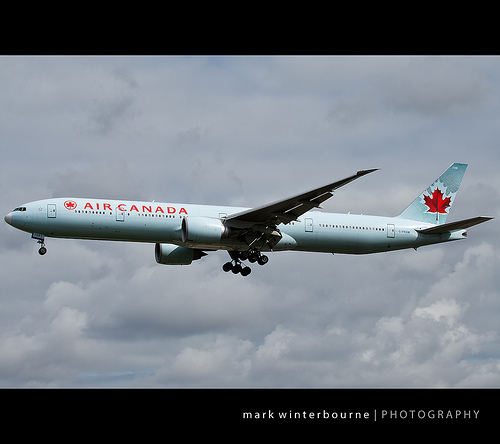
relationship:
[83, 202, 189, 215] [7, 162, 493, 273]
air canada written in plane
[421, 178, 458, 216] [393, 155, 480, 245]
logo on tail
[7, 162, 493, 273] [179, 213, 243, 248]
plane has engine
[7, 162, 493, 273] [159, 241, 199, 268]
plane has engine